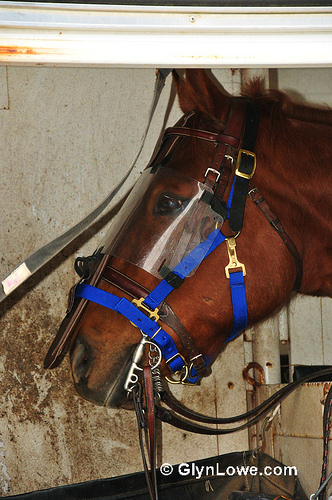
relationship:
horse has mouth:
[64, 68, 332, 410] [96, 360, 127, 410]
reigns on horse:
[80, 279, 219, 385] [64, 80, 326, 419]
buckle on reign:
[235, 149, 258, 177] [219, 100, 267, 228]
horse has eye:
[64, 80, 326, 419] [151, 189, 189, 216]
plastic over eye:
[93, 164, 224, 287] [151, 189, 189, 216]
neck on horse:
[286, 103, 331, 296] [64, 80, 326, 419]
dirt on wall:
[6, 288, 134, 475] [2, 67, 178, 250]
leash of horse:
[5, 80, 154, 319] [64, 80, 326, 419]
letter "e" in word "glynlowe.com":
[249, 462, 258, 478] [175, 455, 301, 481]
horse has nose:
[64, 80, 326, 419] [69, 337, 91, 384]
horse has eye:
[64, 80, 326, 419] [146, 191, 189, 217]